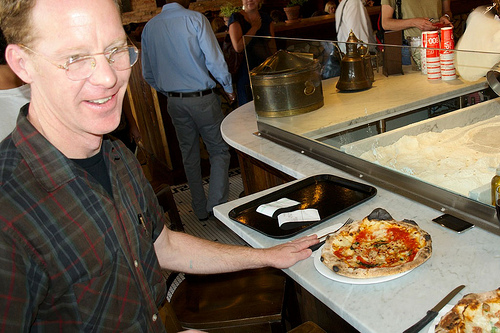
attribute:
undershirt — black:
[64, 151, 136, 198]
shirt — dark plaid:
[36, 131, 194, 328]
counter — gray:
[372, 276, 438, 318]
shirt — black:
[5, 104, 172, 326]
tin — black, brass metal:
[226, 33, 338, 127]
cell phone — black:
[431, 211, 476, 235]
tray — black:
[228, 172, 379, 239]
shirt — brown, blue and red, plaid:
[2, 94, 190, 331]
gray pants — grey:
[159, 84, 258, 213]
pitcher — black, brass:
[335, 29, 374, 93]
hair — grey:
[3, 5, 35, 55]